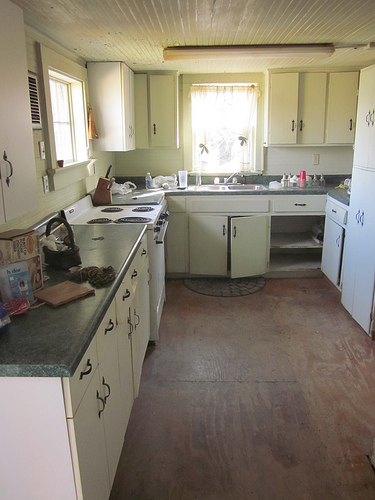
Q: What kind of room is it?
A: It is a kitchen.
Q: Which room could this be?
A: It is a kitchen.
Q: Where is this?
A: This is at the kitchen.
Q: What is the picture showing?
A: It is showing a kitchen.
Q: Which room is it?
A: It is a kitchen.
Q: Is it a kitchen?
A: Yes, it is a kitchen.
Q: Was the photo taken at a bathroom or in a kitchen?
A: It was taken at a kitchen.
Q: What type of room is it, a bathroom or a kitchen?
A: It is a kitchen.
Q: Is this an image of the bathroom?
A: No, the picture is showing the kitchen.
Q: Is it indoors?
A: Yes, it is indoors.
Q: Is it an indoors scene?
A: Yes, it is indoors.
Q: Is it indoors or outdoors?
A: It is indoors.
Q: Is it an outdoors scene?
A: No, it is indoors.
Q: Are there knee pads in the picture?
A: No, there are no knee pads.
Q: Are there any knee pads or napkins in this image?
A: No, there are no knee pads or napkins.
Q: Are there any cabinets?
A: Yes, there is a cabinet.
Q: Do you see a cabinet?
A: Yes, there is a cabinet.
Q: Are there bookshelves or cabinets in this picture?
A: Yes, there is a cabinet.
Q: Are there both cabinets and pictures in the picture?
A: No, there is a cabinet but no pictures.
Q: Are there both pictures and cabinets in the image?
A: No, there is a cabinet but no pictures.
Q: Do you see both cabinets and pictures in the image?
A: No, there is a cabinet but no pictures.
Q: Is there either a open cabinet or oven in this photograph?
A: Yes, there is an open cabinet.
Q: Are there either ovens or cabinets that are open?
A: Yes, the cabinet is open.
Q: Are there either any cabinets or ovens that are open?
A: Yes, the cabinet is open.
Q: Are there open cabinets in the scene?
A: Yes, there is an open cabinet.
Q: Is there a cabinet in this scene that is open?
A: Yes, there is a cabinet that is open.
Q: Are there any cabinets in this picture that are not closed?
A: Yes, there is a open cabinet.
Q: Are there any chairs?
A: No, there are no chairs.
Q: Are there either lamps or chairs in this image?
A: No, there are no chairs or lamps.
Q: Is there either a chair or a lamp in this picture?
A: No, there are no chairs or lamps.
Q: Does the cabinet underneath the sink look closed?
A: No, the cabinet is open.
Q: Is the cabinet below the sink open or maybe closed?
A: The cabinet is open.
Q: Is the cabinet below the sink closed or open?
A: The cabinet is open.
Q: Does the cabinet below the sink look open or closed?
A: The cabinet is open.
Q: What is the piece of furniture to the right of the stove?
A: The piece of furniture is a cabinet.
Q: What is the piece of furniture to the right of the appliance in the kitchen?
A: The piece of furniture is a cabinet.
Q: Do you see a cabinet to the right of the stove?
A: Yes, there is a cabinet to the right of the stove.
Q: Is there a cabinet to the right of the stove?
A: Yes, there is a cabinet to the right of the stove.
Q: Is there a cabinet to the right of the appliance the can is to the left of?
A: Yes, there is a cabinet to the right of the stove.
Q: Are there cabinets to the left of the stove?
A: No, the cabinet is to the right of the stove.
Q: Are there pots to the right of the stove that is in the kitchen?
A: No, there is a cabinet to the right of the stove.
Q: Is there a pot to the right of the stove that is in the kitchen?
A: No, there is a cabinet to the right of the stove.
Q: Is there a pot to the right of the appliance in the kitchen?
A: No, there is a cabinet to the right of the stove.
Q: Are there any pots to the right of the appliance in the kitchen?
A: No, there is a cabinet to the right of the stove.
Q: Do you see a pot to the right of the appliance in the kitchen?
A: No, there is a cabinet to the right of the stove.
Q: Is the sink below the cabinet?
A: No, the cabinet is below the sink.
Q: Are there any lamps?
A: No, there are no lamps.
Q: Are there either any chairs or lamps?
A: No, there are no lamps or chairs.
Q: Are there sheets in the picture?
A: No, there are no sheets.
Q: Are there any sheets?
A: No, there are no sheets.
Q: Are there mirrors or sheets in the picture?
A: No, there are no sheets or mirrors.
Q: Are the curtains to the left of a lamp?
A: No, the curtains are to the left of the cupboard.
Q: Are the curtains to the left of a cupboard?
A: Yes, the curtains are to the left of a cupboard.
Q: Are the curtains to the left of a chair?
A: No, the curtains are to the left of a cupboard.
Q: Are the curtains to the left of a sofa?
A: No, the curtains are to the left of the cabinet.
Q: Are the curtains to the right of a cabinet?
A: Yes, the curtains are to the right of a cabinet.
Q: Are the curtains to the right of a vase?
A: No, the curtains are to the right of a cabinet.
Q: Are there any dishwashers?
A: No, there are no dishwashers.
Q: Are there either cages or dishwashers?
A: No, there are no dishwashers or cages.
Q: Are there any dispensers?
A: No, there are no dispensers.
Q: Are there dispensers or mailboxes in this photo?
A: No, there are no dispensers or mailboxes.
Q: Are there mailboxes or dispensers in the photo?
A: No, there are no dispensers or mailboxes.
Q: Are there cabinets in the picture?
A: Yes, there is a cabinet.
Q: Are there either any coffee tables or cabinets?
A: Yes, there is a cabinet.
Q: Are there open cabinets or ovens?
A: Yes, there is an open cabinet.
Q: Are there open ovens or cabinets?
A: Yes, there is an open cabinet.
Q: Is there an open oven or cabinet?
A: Yes, there is an open cabinet.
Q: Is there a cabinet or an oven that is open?
A: Yes, the cabinet is open.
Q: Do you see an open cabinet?
A: Yes, there is an open cabinet.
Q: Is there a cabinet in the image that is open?
A: Yes, there is a cabinet that is open.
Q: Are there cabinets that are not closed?
A: Yes, there is a open cabinet.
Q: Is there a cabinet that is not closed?
A: Yes, there is a open cabinet.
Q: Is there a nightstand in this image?
A: No, there are no nightstands.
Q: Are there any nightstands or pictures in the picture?
A: No, there are no nightstands or pictures.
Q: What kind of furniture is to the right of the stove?
A: The piece of furniture is a cabinet.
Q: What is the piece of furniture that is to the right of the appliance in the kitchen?
A: The piece of furniture is a cabinet.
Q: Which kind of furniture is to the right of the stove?
A: The piece of furniture is a cabinet.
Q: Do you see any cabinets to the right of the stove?
A: Yes, there is a cabinet to the right of the stove.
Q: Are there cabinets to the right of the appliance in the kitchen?
A: Yes, there is a cabinet to the right of the stove.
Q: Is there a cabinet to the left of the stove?
A: No, the cabinet is to the right of the stove.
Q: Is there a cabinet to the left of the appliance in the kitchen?
A: No, the cabinet is to the right of the stove.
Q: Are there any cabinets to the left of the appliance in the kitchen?
A: No, the cabinet is to the right of the stove.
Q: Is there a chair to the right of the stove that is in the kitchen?
A: No, there is a cabinet to the right of the stove.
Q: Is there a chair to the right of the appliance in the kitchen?
A: No, there is a cabinet to the right of the stove.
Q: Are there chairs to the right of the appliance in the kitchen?
A: No, there is a cabinet to the right of the stove.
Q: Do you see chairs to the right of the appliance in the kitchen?
A: No, there is a cabinet to the right of the stove.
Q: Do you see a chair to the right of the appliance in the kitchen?
A: No, there is a cabinet to the right of the stove.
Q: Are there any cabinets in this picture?
A: Yes, there is a cabinet.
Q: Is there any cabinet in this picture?
A: Yes, there is a cabinet.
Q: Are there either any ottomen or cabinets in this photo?
A: Yes, there is a cabinet.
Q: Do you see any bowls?
A: No, there are no bowls.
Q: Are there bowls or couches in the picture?
A: No, there are no bowls or couches.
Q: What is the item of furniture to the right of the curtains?
A: The piece of furniture is a cabinet.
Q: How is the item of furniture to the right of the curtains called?
A: The piece of furniture is a cabinet.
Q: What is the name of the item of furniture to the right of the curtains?
A: The piece of furniture is a cabinet.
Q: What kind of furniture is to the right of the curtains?
A: The piece of furniture is a cabinet.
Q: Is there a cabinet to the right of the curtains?
A: Yes, there is a cabinet to the right of the curtains.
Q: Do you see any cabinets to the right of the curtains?
A: Yes, there is a cabinet to the right of the curtains.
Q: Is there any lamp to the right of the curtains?
A: No, there is a cabinet to the right of the curtains.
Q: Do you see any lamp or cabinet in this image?
A: Yes, there is a cabinet.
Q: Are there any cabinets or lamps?
A: Yes, there is a cabinet.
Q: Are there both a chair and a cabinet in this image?
A: No, there is a cabinet but no chairs.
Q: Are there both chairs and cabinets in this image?
A: No, there is a cabinet but no chairs.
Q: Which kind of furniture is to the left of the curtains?
A: The piece of furniture is a cabinet.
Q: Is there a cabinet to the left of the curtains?
A: Yes, there is a cabinet to the left of the curtains.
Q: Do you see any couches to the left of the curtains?
A: No, there is a cabinet to the left of the curtains.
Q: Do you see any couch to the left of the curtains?
A: No, there is a cabinet to the left of the curtains.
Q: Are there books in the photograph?
A: No, there are no books.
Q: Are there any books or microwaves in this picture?
A: No, there are no books or microwaves.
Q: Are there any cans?
A: Yes, there is a can.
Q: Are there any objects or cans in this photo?
A: Yes, there is a can.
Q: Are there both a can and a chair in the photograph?
A: No, there is a can but no chairs.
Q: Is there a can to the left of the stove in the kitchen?
A: Yes, there is a can to the left of the stove.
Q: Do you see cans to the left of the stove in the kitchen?
A: Yes, there is a can to the left of the stove.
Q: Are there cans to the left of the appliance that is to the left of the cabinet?
A: Yes, there is a can to the left of the stove.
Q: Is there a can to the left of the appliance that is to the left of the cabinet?
A: Yes, there is a can to the left of the stove.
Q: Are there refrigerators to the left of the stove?
A: No, there is a can to the left of the stove.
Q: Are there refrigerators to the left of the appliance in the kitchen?
A: No, there is a can to the left of the stove.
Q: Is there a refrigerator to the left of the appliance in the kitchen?
A: No, there is a can to the left of the stove.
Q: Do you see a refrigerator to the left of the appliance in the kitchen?
A: No, there is a can to the left of the stove.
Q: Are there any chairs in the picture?
A: No, there are no chairs.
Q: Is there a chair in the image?
A: No, there are no chairs.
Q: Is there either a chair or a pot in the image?
A: No, there are no chairs or pots.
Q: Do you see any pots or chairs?
A: No, there are no chairs or pots.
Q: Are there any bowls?
A: No, there are no bowls.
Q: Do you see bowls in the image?
A: No, there are no bowls.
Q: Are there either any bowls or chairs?
A: No, there are no bowls or chairs.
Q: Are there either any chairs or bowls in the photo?
A: No, there are no bowls or chairs.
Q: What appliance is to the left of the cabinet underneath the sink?
A: The appliance is a stove.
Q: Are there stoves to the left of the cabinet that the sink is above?
A: Yes, there is a stove to the left of the cabinet.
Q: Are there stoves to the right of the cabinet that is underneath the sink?
A: No, the stove is to the left of the cabinet.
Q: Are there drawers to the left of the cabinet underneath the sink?
A: No, there is a stove to the left of the cabinet.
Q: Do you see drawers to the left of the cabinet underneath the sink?
A: No, there is a stove to the left of the cabinet.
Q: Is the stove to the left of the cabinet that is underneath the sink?
A: Yes, the stove is to the left of the cabinet.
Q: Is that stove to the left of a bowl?
A: No, the stove is to the left of the cabinet.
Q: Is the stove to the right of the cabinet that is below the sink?
A: No, the stove is to the left of the cabinet.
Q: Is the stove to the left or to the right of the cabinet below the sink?
A: The stove is to the left of the cabinet.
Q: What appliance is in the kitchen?
A: The appliance is a stove.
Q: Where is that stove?
A: The stove is in the kitchen.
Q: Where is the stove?
A: The stove is in the kitchen.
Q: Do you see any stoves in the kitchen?
A: Yes, there is a stove in the kitchen.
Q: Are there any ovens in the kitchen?
A: No, there is a stove in the kitchen.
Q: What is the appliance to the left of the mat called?
A: The appliance is a stove.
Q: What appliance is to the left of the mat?
A: The appliance is a stove.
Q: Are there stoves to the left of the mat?
A: Yes, there is a stove to the left of the mat.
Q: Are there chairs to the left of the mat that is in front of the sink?
A: No, there is a stove to the left of the mat.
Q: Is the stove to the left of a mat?
A: Yes, the stove is to the left of a mat.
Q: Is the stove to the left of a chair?
A: No, the stove is to the left of a mat.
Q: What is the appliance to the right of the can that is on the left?
A: The appliance is a stove.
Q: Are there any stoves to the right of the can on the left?
A: Yes, there is a stove to the right of the can.